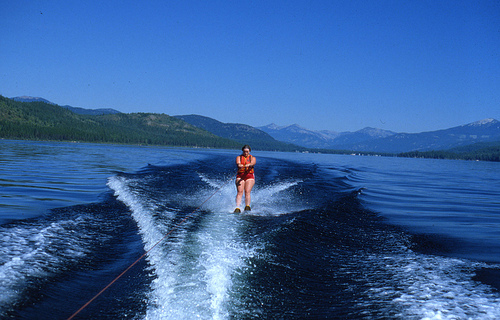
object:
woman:
[232, 145, 256, 214]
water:
[0, 139, 499, 320]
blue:
[0, 141, 497, 320]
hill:
[0, 88, 120, 118]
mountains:
[0, 95, 499, 154]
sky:
[0, 21, 499, 129]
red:
[237, 172, 254, 180]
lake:
[0, 140, 497, 319]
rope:
[70, 165, 247, 319]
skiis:
[243, 206, 253, 214]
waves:
[0, 173, 499, 319]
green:
[10, 103, 46, 137]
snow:
[460, 116, 499, 131]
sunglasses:
[241, 151, 249, 154]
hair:
[240, 144, 251, 154]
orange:
[235, 157, 257, 179]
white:
[260, 179, 294, 198]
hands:
[242, 163, 251, 169]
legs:
[243, 179, 255, 211]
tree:
[0, 95, 245, 150]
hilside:
[0, 102, 230, 147]